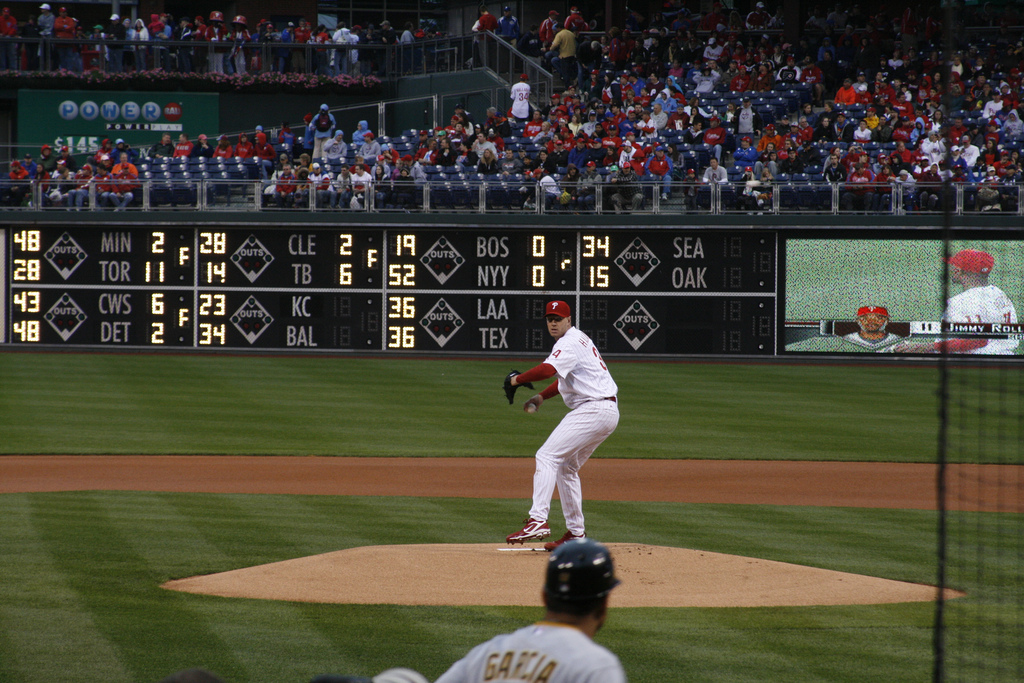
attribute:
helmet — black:
[540, 527, 620, 632]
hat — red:
[532, 290, 574, 332]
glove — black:
[502, 363, 540, 403]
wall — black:
[33, 131, 479, 326]